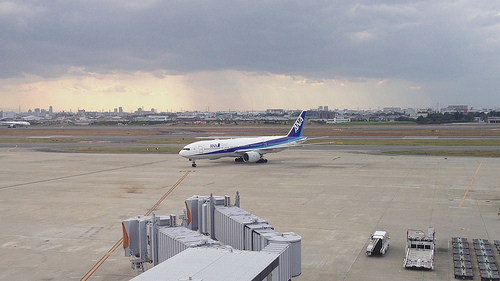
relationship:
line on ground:
[456, 160, 488, 215] [1, 121, 497, 279]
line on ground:
[73, 167, 193, 279] [1, 121, 497, 279]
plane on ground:
[177, 110, 309, 168] [1, 121, 497, 279]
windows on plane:
[170, 144, 201, 158] [161, 93, 318, 185]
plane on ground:
[165, 105, 332, 178] [1, 121, 497, 279]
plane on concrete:
[177, 110, 309, 168] [0, 163, 500, 217]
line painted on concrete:
[81, 167, 192, 279] [0, 163, 500, 217]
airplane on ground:
[161, 92, 301, 183] [37, 91, 485, 262]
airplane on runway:
[0, 116, 32, 129] [6, 116, 496, 279]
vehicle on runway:
[363, 225, 394, 259] [270, 142, 499, 152]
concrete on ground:
[0, 163, 500, 217] [2, 149, 498, 279]